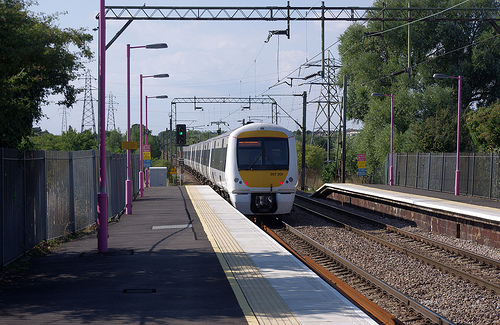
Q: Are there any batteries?
A: No, there are no batteries.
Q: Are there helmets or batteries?
A: No, there are no batteries or helmets.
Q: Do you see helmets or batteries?
A: No, there are no batteries or helmets.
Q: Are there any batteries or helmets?
A: No, there are no batteries or helmets.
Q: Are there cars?
A: No, there are no cars.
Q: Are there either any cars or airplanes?
A: No, there are no cars or airplanes.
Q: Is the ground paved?
A: Yes, the ground is paved.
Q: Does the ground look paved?
A: Yes, the ground is paved.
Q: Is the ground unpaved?
A: No, the ground is paved.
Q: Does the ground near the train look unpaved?
A: No, the ground is paved.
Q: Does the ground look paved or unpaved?
A: The ground is paved.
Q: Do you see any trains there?
A: Yes, there is a train.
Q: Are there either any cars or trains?
A: Yes, there is a train.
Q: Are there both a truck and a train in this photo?
A: No, there is a train but no trucks.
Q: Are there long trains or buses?
A: Yes, there is a long train.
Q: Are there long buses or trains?
A: Yes, there is a long train.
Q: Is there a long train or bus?
A: Yes, there is a long train.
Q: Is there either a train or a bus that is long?
A: Yes, the train is long.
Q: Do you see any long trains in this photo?
A: Yes, there is a long train.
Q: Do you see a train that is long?
A: Yes, there is a train that is long.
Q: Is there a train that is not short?
A: Yes, there is a long train.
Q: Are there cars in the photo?
A: No, there are no cars.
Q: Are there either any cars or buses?
A: No, there are no cars or buses.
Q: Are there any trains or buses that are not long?
A: No, there is a train but it is long.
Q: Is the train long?
A: Yes, the train is long.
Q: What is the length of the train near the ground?
A: The train is long.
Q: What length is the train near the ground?
A: The train is long.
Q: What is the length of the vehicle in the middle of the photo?
A: The train is long.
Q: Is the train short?
A: No, the train is long.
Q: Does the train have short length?
A: No, the train is long.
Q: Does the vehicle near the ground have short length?
A: No, the train is long.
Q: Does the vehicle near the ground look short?
A: No, the train is long.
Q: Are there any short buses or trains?
A: No, there is a train but it is long.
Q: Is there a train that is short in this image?
A: No, there is a train but it is long.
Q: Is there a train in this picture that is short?
A: No, there is a train but it is long.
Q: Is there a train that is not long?
A: No, there is a train but it is long.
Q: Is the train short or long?
A: The train is long.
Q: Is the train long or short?
A: The train is long.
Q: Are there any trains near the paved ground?
A: Yes, there is a train near the ground.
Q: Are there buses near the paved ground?
A: No, there is a train near the ground.